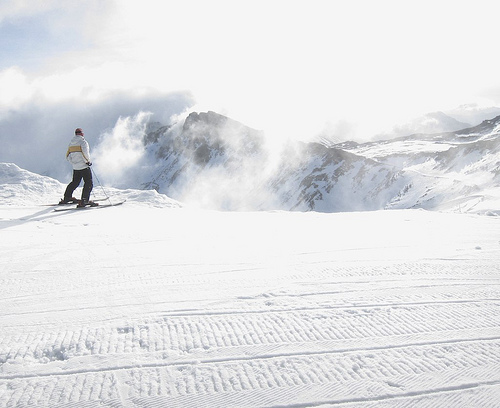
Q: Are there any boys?
A: No, there are no boys.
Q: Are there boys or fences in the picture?
A: No, there are no boys or fences.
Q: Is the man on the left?
A: Yes, the man is on the left of the image.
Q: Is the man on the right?
A: No, the man is on the left of the image.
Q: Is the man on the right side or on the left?
A: The man is on the left of the image.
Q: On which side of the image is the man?
A: The man is on the left of the image.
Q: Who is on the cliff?
A: The man is on the cliff.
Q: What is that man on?
A: The man is on the cliff.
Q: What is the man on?
A: The man is on the cliff.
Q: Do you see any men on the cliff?
A: Yes, there is a man on the cliff.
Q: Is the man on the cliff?
A: Yes, the man is on the cliff.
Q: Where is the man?
A: The man is in the snow.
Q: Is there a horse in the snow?
A: No, there is a man in the snow.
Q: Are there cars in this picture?
A: No, there are no cars.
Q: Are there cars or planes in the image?
A: No, there are no cars or planes.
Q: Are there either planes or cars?
A: No, there are no cars or planes.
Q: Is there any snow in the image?
A: Yes, there is snow.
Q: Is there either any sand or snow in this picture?
A: Yes, there is snow.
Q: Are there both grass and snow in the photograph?
A: No, there is snow but no grass.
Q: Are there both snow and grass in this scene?
A: No, there is snow but no grass.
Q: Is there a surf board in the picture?
A: No, there are no surfboards.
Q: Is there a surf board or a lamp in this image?
A: No, there are no surfboards or lamps.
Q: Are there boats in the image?
A: No, there are no boats.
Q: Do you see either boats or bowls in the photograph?
A: No, there are no boats or bowls.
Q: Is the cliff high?
A: Yes, the cliff is high.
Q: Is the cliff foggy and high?
A: Yes, the cliff is foggy and high.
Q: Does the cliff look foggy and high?
A: Yes, the cliff is foggy and high.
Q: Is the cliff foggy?
A: Yes, the cliff is foggy.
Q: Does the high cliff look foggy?
A: Yes, the cliff is foggy.